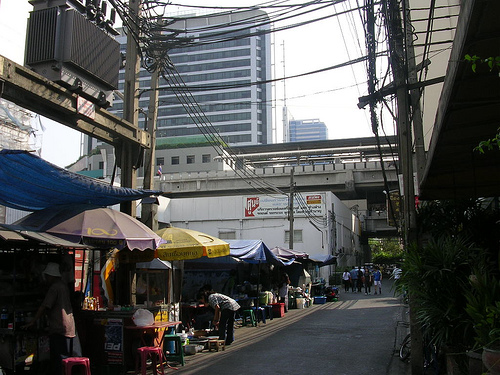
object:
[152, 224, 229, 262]
umbrella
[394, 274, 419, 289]
leaves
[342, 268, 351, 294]
people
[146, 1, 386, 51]
lines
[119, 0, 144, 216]
pole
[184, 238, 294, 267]
tarp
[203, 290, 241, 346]
person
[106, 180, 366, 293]
building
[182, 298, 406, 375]
shadow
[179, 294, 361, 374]
lines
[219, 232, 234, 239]
windows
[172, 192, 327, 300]
side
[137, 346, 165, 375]
stool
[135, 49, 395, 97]
wires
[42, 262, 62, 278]
hat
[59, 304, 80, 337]
sun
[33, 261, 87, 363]
man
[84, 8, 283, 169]
building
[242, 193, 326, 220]
sign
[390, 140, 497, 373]
bush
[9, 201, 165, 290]
umbrella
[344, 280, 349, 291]
pants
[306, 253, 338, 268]
tarp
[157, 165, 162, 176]
flag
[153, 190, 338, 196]
top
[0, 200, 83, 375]
restaurants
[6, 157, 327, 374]
market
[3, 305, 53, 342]
part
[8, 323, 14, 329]
pepsi sign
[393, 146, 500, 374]
bunch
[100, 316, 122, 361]
signs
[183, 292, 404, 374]
street